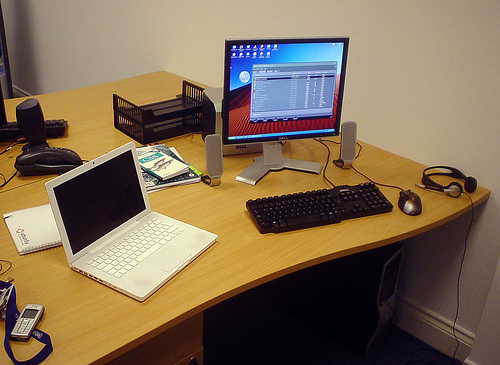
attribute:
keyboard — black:
[235, 173, 429, 230]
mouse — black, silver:
[384, 175, 434, 220]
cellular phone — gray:
[5, 298, 47, 345]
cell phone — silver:
[11, 304, 46, 344]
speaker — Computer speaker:
[195, 127, 267, 204]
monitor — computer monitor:
[218, 27, 382, 185]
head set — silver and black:
[421, 162, 478, 201]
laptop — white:
[42, 141, 217, 301]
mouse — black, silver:
[398, 185, 423, 216]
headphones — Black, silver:
[413, 155, 481, 204]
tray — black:
[103, 79, 213, 145]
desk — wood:
[0, 69, 485, 357]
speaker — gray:
[328, 117, 359, 171]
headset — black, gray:
[407, 142, 477, 199]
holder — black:
[113, 75, 208, 139]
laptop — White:
[31, 132, 214, 317]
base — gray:
[236, 136, 325, 184]